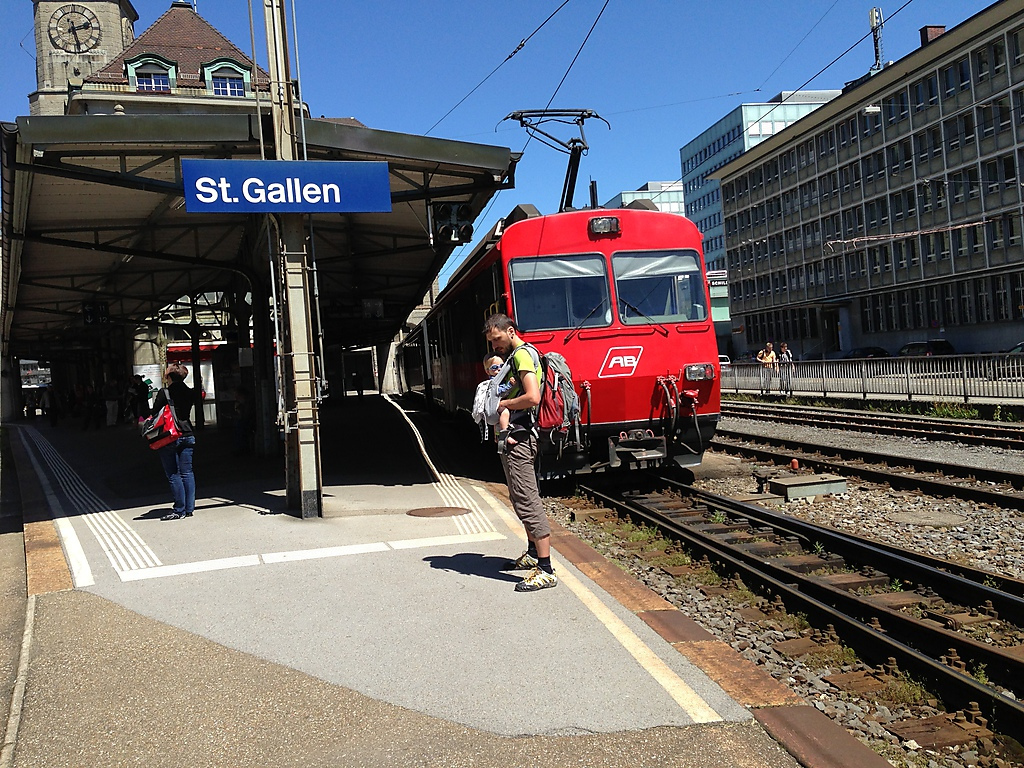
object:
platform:
[389, 578, 663, 734]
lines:
[186, 528, 410, 574]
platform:
[135, 349, 483, 703]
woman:
[135, 357, 196, 520]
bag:
[135, 406, 186, 453]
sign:
[176, 156, 392, 214]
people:
[751, 330, 801, 389]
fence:
[789, 353, 929, 403]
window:
[969, 39, 998, 67]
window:
[129, 66, 176, 93]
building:
[0, 0, 303, 125]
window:
[210, 72, 245, 97]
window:
[994, 202, 1021, 250]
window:
[963, 216, 987, 251]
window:
[882, 229, 895, 272]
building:
[678, 0, 1022, 369]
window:
[910, 235, 924, 265]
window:
[784, 227, 795, 254]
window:
[832, 212, 843, 232]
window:
[863, 200, 880, 231]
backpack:
[540, 351, 578, 441]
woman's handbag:
[134, 380, 192, 460]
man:
[468, 315, 575, 591]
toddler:
[474, 346, 516, 447]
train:
[393, 208, 724, 496]